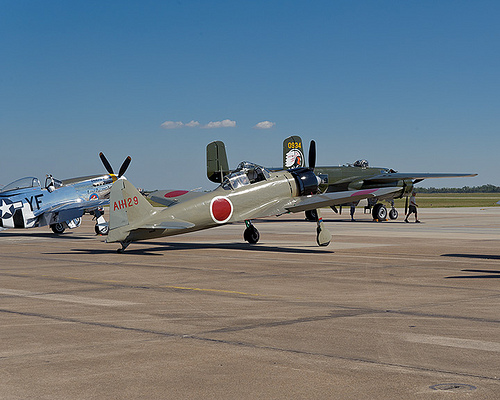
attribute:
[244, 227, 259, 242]
plane wheel — large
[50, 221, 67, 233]
plane wheel — large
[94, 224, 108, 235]
plane wheel — large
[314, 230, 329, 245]
plane wheel — large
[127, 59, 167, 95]
sky — blue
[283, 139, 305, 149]
numbers — yellow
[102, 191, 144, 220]
numbers — red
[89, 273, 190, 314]
pavement — pavemented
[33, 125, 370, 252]
planes — three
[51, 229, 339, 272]
shadow — dark, long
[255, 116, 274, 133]
cloud — white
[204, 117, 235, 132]
cloud — white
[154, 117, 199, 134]
cloud — white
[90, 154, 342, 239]
plane — grey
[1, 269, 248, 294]
stripe — yellow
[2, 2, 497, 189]
sky — blue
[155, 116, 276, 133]
clouds — white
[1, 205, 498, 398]
concrete — gray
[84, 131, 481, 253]
plane — blue, military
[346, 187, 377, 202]
stripe — red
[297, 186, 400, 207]
wing — grey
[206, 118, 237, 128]
cloud — white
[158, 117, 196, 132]
cloud — white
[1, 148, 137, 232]
plane — cemented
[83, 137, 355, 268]
aircraft — olive colored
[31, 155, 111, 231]
plane — blue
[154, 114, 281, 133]
clouds — white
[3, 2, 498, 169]
sky — blue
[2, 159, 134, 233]
plane — silver, blue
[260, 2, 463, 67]
sky — blue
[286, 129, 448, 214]
plane — green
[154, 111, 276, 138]
clouds — small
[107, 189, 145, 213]
lettering — red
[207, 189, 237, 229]
dot — red, white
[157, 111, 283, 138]
cloud — white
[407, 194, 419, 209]
shirt — white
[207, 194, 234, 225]
outline — white